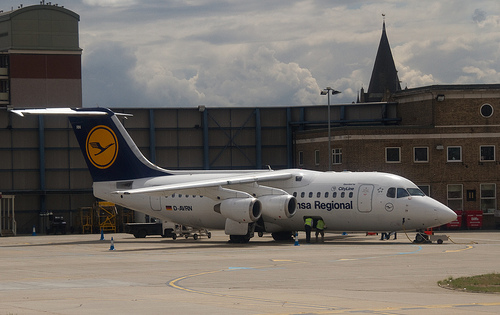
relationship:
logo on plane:
[84, 124, 119, 170] [6, 102, 460, 245]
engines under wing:
[212, 182, 300, 237] [110, 172, 293, 196]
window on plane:
[386, 184, 397, 200] [6, 102, 460, 245]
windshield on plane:
[406, 186, 429, 197] [6, 102, 460, 245]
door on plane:
[356, 180, 375, 213] [6, 102, 460, 245]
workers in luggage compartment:
[304, 216, 325, 243] [301, 212, 328, 231]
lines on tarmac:
[167, 239, 498, 313] [1, 230, 500, 313]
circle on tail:
[84, 124, 119, 170] [68, 104, 177, 180]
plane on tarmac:
[6, 102, 460, 245] [1, 230, 500, 313]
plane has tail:
[6, 102, 460, 245] [68, 104, 177, 180]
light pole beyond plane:
[320, 85, 341, 172] [6, 102, 460, 245]